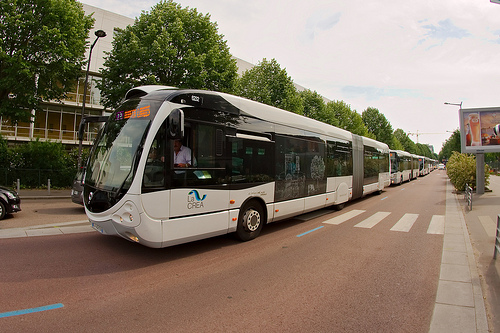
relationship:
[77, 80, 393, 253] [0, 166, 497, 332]
bus on road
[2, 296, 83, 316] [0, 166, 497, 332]
line on road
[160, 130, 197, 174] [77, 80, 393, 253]
driver sitting inside bus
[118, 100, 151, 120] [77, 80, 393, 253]
sign on bus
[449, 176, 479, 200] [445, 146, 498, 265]
barrier on road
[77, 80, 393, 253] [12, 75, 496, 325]
bus in city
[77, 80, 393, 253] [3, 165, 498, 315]
bus on street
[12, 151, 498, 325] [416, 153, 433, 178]
city owns bus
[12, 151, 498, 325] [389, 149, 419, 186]
city owns bus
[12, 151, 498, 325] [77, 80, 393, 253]
city owns bus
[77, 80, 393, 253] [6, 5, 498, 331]
bus operates daytime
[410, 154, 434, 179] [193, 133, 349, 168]
bus carry commuters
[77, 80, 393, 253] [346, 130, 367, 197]
bus has center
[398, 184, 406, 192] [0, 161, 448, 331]
line on road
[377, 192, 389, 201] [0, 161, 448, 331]
line on road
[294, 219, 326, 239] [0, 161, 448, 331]
line on road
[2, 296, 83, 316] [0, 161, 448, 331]
line on road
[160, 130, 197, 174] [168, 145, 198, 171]
driver wears shirt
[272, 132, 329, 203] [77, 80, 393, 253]
ads side bus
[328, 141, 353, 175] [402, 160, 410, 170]
ads side ads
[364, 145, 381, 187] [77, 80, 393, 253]
ads side bus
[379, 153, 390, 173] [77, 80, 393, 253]
ads side bus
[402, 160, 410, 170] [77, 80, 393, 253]
ads side bus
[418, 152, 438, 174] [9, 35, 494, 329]
bus in city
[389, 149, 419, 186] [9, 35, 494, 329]
bus in city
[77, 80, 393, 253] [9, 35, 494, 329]
bus in city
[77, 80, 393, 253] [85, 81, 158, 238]
bus has front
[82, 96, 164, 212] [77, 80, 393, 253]
windshield on bus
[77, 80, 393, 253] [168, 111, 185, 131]
bus has mirror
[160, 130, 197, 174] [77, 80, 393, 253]
driver of bus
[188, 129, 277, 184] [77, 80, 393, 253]
windows of bus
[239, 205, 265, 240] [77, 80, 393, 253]
wheel of bus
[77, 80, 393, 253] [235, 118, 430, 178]
bus carrying passengers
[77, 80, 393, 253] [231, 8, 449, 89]
bus running daytime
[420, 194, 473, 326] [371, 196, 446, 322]
sidewalk in road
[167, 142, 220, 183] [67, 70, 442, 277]
mirror of bus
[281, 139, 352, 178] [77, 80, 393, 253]
windows of bus